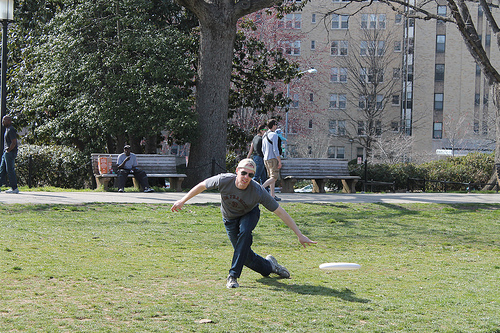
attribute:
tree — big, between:
[181, 12, 237, 161]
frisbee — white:
[318, 262, 358, 271]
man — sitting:
[116, 146, 141, 192]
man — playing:
[166, 150, 370, 291]